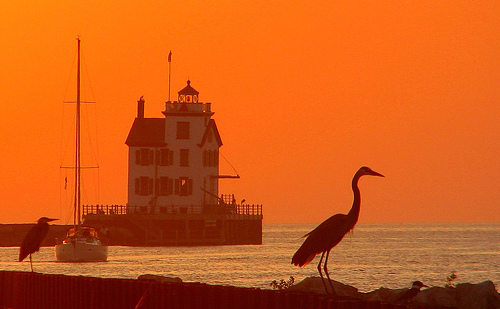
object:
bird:
[15, 214, 51, 271]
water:
[0, 224, 499, 289]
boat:
[56, 27, 110, 262]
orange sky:
[0, 0, 498, 225]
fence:
[0, 270, 499, 309]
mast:
[74, 36, 82, 236]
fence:
[83, 202, 262, 222]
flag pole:
[167, 49, 172, 101]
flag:
[168, 50, 173, 62]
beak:
[366, 168, 385, 181]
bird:
[291, 167, 387, 303]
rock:
[294, 276, 500, 308]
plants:
[269, 275, 297, 291]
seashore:
[0, 246, 499, 309]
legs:
[317, 248, 337, 296]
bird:
[386, 280, 431, 308]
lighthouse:
[123, 76, 223, 218]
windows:
[135, 120, 194, 197]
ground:
[371, 95, 455, 209]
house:
[123, 81, 222, 220]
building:
[80, 49, 263, 246]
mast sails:
[72, 38, 84, 230]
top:
[125, 80, 224, 148]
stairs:
[122, 214, 168, 239]